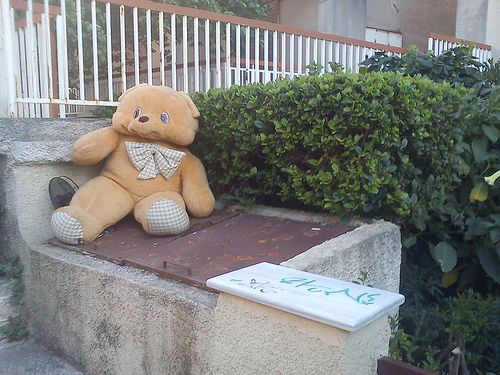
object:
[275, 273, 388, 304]
grafitti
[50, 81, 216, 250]
bear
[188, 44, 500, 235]
shrubs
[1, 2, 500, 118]
railing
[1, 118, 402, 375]
wall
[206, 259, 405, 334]
tile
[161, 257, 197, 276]
handle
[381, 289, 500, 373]
plant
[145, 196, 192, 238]
foot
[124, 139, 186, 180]
bow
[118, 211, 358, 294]
door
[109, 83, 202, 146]
head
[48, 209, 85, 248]
foot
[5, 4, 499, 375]
photo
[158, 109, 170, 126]
eyes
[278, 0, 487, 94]
building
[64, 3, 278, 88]
tree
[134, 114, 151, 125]
nose